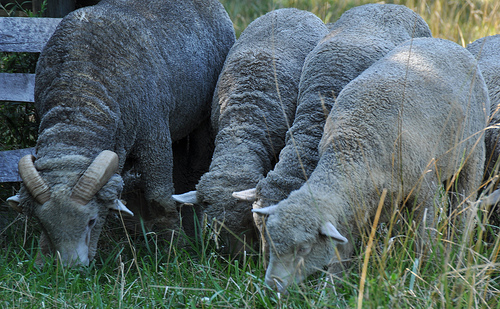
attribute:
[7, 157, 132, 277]
head — down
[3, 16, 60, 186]
fence — wooden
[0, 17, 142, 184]
fence — old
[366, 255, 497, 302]
grass — tall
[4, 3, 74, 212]
fence — grey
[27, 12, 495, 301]
sheep — grey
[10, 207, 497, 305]
grass — long, green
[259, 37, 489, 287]
sheep — grey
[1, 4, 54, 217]
fence — wooden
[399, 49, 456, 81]
sun reflection — shiny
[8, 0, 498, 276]
sheeps — wooly, black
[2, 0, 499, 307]
grass — brown, tall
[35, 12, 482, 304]
goats — eating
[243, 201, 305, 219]
goats ear — white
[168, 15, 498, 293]
sheep — wooly, black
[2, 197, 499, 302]
grass — green, tall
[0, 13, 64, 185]
fence — wooden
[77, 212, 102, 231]
eye — black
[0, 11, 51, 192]
three boards — gray